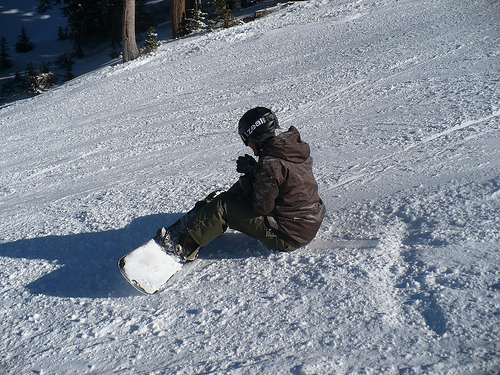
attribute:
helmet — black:
[232, 105, 281, 147]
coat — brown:
[230, 120, 330, 250]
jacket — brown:
[243, 125, 329, 246]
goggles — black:
[234, 127, 246, 140]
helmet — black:
[213, 87, 298, 147]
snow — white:
[2, 0, 498, 375]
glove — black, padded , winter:
[234, 152, 260, 175]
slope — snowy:
[0, 1, 497, 371]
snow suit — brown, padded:
[173, 126, 331, 253]